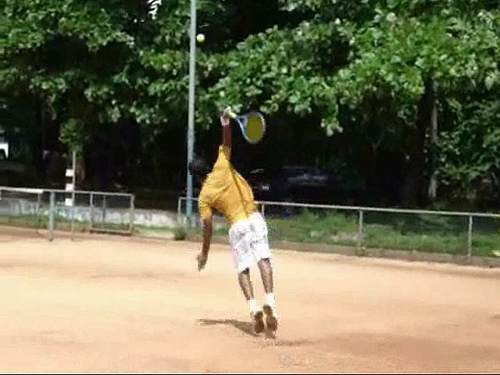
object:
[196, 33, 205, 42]
ball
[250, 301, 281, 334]
tennis shoe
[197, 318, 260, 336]
shadow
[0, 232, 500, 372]
ground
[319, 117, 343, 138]
leaves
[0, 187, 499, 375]
court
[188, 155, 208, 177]
head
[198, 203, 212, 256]
arm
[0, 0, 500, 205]
trees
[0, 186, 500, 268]
fence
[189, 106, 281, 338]
ball player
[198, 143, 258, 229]
shirt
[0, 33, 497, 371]
tennis scene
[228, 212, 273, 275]
shorts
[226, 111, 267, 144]
racket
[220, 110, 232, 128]
hand